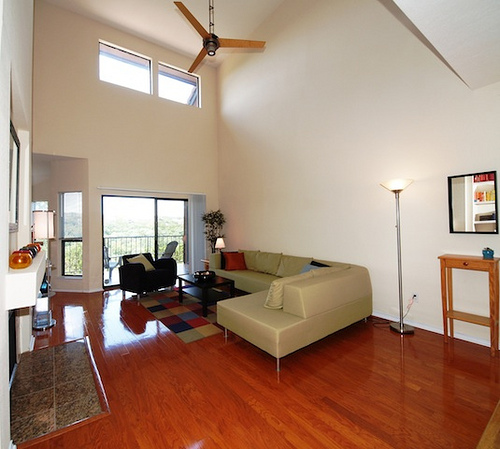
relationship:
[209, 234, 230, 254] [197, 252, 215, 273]
lamp on table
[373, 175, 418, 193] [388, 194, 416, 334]
lamp on a pole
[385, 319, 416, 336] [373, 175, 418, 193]
base of a lamp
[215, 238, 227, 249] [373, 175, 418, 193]
lamp of a lamp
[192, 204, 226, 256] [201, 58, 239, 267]
plant in corner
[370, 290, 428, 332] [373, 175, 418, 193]
power cord to lamp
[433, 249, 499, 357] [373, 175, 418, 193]
wooden table by lamp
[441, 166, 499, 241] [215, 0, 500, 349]
mirror on wall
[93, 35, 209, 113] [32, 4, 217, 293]
window in a wall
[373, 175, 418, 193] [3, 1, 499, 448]
lamp in living room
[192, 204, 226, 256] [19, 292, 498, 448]
plant on floor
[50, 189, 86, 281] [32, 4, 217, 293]
window on wall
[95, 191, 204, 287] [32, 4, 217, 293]
window on wall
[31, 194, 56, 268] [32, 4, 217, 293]
window on wall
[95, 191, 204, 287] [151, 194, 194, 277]
window has a sliding pane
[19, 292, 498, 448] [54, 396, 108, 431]
floor has tile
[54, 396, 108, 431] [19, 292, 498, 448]
tile on floor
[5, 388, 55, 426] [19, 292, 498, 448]
tile on floor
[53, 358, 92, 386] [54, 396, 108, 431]
tile in tile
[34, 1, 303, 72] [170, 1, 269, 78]
ceiling has a fan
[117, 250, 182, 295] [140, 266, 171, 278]
chair with one seat